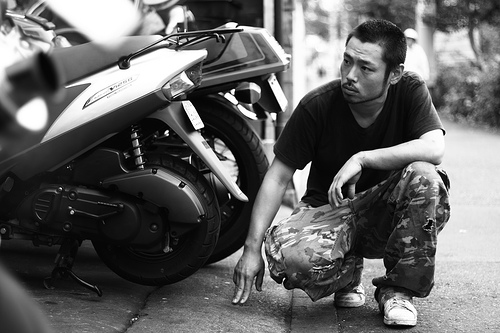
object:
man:
[231, 20, 448, 328]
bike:
[0, 24, 245, 296]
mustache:
[338, 82, 361, 95]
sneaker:
[380, 291, 416, 327]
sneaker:
[328, 275, 367, 308]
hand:
[325, 151, 361, 209]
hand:
[227, 249, 265, 307]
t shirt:
[271, 70, 442, 209]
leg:
[360, 160, 448, 301]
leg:
[265, 203, 353, 291]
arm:
[363, 82, 448, 169]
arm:
[244, 106, 315, 254]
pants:
[266, 160, 449, 296]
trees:
[436, 5, 499, 68]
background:
[298, 0, 499, 122]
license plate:
[179, 98, 206, 132]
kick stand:
[57, 262, 107, 297]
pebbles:
[223, 281, 231, 285]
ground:
[7, 116, 497, 331]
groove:
[112, 287, 156, 333]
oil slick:
[45, 301, 57, 305]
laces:
[385, 287, 410, 308]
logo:
[83, 76, 138, 110]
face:
[338, 38, 394, 103]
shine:
[83, 37, 131, 54]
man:
[399, 26, 430, 77]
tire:
[87, 152, 222, 288]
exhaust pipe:
[3, 33, 71, 143]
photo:
[2, 3, 499, 330]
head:
[334, 16, 412, 106]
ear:
[389, 63, 405, 86]